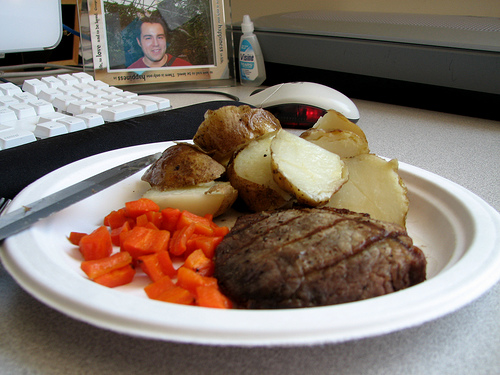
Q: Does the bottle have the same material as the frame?
A: No, the bottle is made of plastic and the frame is made of metal.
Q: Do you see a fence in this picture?
A: No, there are no fences.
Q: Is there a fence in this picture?
A: No, there are no fences.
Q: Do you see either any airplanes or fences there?
A: No, there are no fences or airplanes.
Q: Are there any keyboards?
A: Yes, there is a keyboard.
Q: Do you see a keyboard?
A: Yes, there is a keyboard.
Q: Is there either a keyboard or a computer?
A: Yes, there is a keyboard.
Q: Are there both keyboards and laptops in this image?
A: No, there is a keyboard but no laptops.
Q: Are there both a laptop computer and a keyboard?
A: No, there is a keyboard but no laptops.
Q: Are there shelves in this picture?
A: No, there are no shelves.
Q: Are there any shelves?
A: No, there are no shelves.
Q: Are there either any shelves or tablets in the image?
A: No, there are no shelves or tablets.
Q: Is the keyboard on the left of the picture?
A: Yes, the keyboard is on the left of the image.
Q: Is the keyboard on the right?
A: No, the keyboard is on the left of the image.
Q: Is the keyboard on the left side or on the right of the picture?
A: The keyboard is on the left of the image.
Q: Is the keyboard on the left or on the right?
A: The keyboard is on the left of the image.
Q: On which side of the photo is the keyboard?
A: The keyboard is on the left of the image.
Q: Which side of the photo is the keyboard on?
A: The keyboard is on the left of the image.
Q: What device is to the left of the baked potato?
A: The device is a keyboard.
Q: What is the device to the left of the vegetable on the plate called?
A: The device is a keyboard.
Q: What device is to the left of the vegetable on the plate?
A: The device is a keyboard.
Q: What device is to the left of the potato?
A: The device is a keyboard.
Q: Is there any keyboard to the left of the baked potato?
A: Yes, there is a keyboard to the left of the potato.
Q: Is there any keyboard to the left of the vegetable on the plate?
A: Yes, there is a keyboard to the left of the potato.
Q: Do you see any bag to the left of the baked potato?
A: No, there is a keyboard to the left of the potato.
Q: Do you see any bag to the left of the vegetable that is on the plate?
A: No, there is a keyboard to the left of the potato.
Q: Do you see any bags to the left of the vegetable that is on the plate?
A: No, there is a keyboard to the left of the potato.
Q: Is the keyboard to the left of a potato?
A: Yes, the keyboard is to the left of a potato.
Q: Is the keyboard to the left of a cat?
A: No, the keyboard is to the left of a potato.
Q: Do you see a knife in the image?
A: Yes, there is a knife.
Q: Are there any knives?
A: Yes, there is a knife.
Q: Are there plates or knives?
A: Yes, there is a knife.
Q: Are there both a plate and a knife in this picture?
A: Yes, there are both a knife and a plate.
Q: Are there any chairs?
A: No, there are no chairs.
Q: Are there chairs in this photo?
A: No, there are no chairs.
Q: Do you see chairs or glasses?
A: No, there are no chairs or glasses.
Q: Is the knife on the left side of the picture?
A: Yes, the knife is on the left of the image.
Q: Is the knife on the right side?
A: No, the knife is on the left of the image.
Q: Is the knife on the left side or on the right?
A: The knife is on the left of the image.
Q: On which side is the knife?
A: The knife is on the left of the image.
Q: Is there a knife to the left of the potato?
A: Yes, there is a knife to the left of the potato.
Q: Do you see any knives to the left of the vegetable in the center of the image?
A: Yes, there is a knife to the left of the potato.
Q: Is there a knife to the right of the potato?
A: No, the knife is to the left of the potato.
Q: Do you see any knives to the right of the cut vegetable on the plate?
A: No, the knife is to the left of the potato.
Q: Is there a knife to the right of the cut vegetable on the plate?
A: No, the knife is to the left of the potato.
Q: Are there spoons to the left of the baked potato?
A: No, there is a knife to the left of the potato.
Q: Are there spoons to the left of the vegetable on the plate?
A: No, there is a knife to the left of the potato.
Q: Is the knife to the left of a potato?
A: Yes, the knife is to the left of a potato.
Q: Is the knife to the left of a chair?
A: No, the knife is to the left of a potato.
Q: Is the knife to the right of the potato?
A: No, the knife is to the left of the potato.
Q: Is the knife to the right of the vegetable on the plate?
A: No, the knife is to the left of the potato.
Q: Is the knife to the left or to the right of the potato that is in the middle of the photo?
A: The knife is to the left of the potato.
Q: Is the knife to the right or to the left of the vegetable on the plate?
A: The knife is to the left of the potato.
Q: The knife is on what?
A: The knife is on the plate.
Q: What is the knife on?
A: The knife is on the plate.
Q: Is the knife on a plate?
A: Yes, the knife is on a plate.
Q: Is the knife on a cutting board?
A: No, the knife is on a plate.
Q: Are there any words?
A: Yes, there are words.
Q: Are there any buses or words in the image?
A: Yes, there are words.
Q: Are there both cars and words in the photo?
A: No, there are words but no cars.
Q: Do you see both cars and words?
A: No, there are words but no cars.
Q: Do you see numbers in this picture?
A: No, there are no numbers.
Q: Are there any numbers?
A: No, there are no numbers.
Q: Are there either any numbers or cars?
A: No, there are no numbers or cars.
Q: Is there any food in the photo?
A: Yes, there is food.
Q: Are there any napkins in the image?
A: No, there are no napkins.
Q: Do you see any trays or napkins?
A: No, there are no napkins or trays.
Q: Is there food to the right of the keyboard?
A: Yes, there is food to the right of the keyboard.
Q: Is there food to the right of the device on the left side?
A: Yes, there is food to the right of the keyboard.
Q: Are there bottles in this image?
A: Yes, there is a bottle.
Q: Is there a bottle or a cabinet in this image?
A: Yes, there is a bottle.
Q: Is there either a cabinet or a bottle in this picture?
A: Yes, there is a bottle.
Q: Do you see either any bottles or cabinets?
A: Yes, there is a bottle.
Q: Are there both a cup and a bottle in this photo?
A: No, there is a bottle but no cups.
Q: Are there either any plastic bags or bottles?
A: Yes, there is a plastic bottle.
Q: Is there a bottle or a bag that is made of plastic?
A: Yes, the bottle is made of plastic.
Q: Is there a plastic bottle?
A: Yes, there is a bottle that is made of plastic.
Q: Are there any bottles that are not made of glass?
A: Yes, there is a bottle that is made of plastic.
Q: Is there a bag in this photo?
A: No, there are no bags.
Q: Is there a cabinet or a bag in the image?
A: No, there are no bags or cabinets.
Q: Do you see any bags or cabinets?
A: No, there are no bags or cabinets.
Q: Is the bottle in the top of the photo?
A: Yes, the bottle is in the top of the image.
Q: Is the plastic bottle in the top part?
A: Yes, the bottle is in the top of the image.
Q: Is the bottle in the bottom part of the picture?
A: No, the bottle is in the top of the image.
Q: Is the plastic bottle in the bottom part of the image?
A: No, the bottle is in the top of the image.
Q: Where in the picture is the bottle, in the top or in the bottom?
A: The bottle is in the top of the image.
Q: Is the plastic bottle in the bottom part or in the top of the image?
A: The bottle is in the top of the image.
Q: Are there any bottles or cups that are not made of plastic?
A: No, there is a bottle but it is made of plastic.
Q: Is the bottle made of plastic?
A: Yes, the bottle is made of plastic.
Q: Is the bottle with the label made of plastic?
A: Yes, the bottle is made of plastic.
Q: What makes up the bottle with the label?
A: The bottle is made of plastic.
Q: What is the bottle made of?
A: The bottle is made of plastic.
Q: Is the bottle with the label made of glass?
A: No, the bottle is made of plastic.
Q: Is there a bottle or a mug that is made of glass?
A: No, there is a bottle but it is made of plastic.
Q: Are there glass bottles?
A: No, there is a bottle but it is made of plastic.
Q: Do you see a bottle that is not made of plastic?
A: No, there is a bottle but it is made of plastic.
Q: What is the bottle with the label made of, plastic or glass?
A: The bottle is made of plastic.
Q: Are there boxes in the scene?
A: No, there are no boxes.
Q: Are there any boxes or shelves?
A: No, there are no boxes or shelves.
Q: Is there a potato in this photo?
A: Yes, there is a potato.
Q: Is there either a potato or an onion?
A: Yes, there is a potato.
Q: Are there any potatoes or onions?
A: Yes, there is a potato.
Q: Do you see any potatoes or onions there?
A: Yes, there is a potato.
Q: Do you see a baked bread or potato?
A: Yes, there is a baked potato.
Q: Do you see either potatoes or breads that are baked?
A: Yes, the potato is baked.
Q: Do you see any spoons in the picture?
A: No, there are no spoons.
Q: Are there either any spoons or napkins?
A: No, there are no spoons or napkins.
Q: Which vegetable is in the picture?
A: The vegetable is a potato.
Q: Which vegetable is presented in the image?
A: The vegetable is a potato.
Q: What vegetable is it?
A: The vegetable is a potato.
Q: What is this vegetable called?
A: This is a potato.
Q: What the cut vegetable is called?
A: The vegetable is a potato.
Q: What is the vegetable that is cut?
A: The vegetable is a potato.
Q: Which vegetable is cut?
A: The vegetable is a potato.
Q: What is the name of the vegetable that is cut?
A: The vegetable is a potato.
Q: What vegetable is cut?
A: The vegetable is a potato.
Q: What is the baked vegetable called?
A: The vegetable is a potato.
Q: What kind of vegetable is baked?
A: The vegetable is a potato.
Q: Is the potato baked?
A: Yes, the potato is baked.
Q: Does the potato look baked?
A: Yes, the potato is baked.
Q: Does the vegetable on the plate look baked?
A: Yes, the potato is baked.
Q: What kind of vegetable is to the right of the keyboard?
A: The vegetable is a potato.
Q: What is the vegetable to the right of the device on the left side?
A: The vegetable is a potato.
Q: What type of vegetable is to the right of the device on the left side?
A: The vegetable is a potato.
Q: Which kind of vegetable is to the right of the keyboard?
A: The vegetable is a potato.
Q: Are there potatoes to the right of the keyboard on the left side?
A: Yes, there is a potato to the right of the keyboard.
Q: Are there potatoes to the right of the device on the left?
A: Yes, there is a potato to the right of the keyboard.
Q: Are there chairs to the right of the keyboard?
A: No, there is a potato to the right of the keyboard.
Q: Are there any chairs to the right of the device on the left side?
A: No, there is a potato to the right of the keyboard.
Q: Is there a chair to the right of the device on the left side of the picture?
A: No, there is a potato to the right of the keyboard.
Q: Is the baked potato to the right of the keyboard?
A: Yes, the potato is to the right of the keyboard.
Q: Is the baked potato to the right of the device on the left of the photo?
A: Yes, the potato is to the right of the keyboard.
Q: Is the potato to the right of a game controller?
A: No, the potato is to the right of the keyboard.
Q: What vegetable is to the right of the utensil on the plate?
A: The vegetable is a potato.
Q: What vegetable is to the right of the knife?
A: The vegetable is a potato.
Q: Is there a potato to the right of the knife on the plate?
A: Yes, there is a potato to the right of the knife.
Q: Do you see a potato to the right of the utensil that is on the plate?
A: Yes, there is a potato to the right of the knife.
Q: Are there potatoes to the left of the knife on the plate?
A: No, the potato is to the right of the knife.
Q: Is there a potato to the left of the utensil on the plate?
A: No, the potato is to the right of the knife.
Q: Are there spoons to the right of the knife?
A: No, there is a potato to the right of the knife.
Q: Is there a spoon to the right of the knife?
A: No, there is a potato to the right of the knife.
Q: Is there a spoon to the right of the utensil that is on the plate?
A: No, there is a potato to the right of the knife.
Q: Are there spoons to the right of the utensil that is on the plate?
A: No, there is a potato to the right of the knife.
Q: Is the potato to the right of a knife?
A: Yes, the potato is to the right of a knife.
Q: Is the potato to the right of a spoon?
A: No, the potato is to the right of a knife.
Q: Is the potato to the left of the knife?
A: No, the potato is to the right of the knife.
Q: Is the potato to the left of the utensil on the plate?
A: No, the potato is to the right of the knife.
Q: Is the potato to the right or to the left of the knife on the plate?
A: The potato is to the right of the knife.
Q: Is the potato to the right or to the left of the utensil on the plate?
A: The potato is to the right of the knife.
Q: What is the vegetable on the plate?
A: The vegetable is a potato.